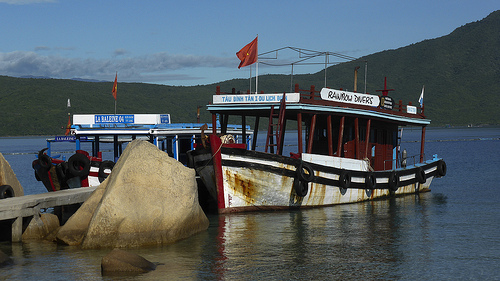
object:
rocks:
[0, 137, 209, 278]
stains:
[214, 160, 439, 203]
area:
[43, 132, 255, 167]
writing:
[95, 112, 129, 124]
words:
[326, 91, 352, 102]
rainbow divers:
[328, 92, 376, 105]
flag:
[234, 37, 259, 69]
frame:
[252, 47, 366, 98]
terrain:
[2, 11, 500, 132]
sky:
[1, 1, 499, 86]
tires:
[29, 148, 98, 184]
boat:
[191, 36, 445, 214]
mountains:
[1, 8, 499, 138]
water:
[0, 129, 499, 278]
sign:
[212, 92, 295, 104]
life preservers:
[293, 159, 448, 203]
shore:
[44, 131, 256, 169]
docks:
[3, 139, 208, 251]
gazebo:
[217, 47, 430, 118]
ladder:
[378, 77, 391, 103]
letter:
[353, 95, 359, 103]